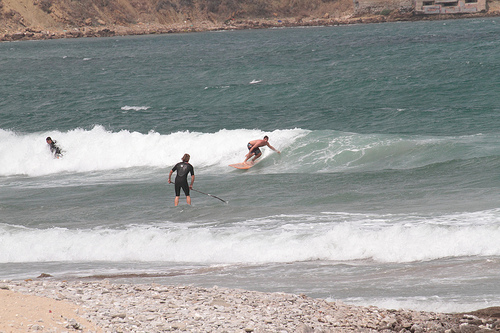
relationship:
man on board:
[235, 132, 279, 161] [230, 160, 258, 172]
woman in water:
[162, 148, 203, 207] [1, 20, 486, 304]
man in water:
[235, 132, 279, 161] [1, 20, 486, 304]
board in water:
[230, 160, 258, 172] [1, 20, 486, 304]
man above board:
[235, 132, 279, 161] [230, 160, 258, 172]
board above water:
[230, 160, 258, 172] [1, 20, 486, 304]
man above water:
[235, 132, 279, 161] [1, 20, 486, 304]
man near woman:
[235, 132, 279, 161] [162, 148, 203, 207]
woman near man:
[162, 148, 203, 207] [235, 132, 279, 161]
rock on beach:
[92, 287, 382, 327] [3, 253, 481, 332]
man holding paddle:
[163, 152, 198, 211] [170, 181, 221, 201]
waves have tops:
[6, 114, 496, 177] [70, 129, 170, 167]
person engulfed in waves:
[42, 136, 67, 155] [0, 114, 500, 177]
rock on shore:
[0, 280, 500, 331] [0, 279, 495, 330]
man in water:
[163, 152, 198, 211] [9, 32, 496, 250]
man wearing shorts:
[244, 136, 276, 161] [246, 142, 259, 160]